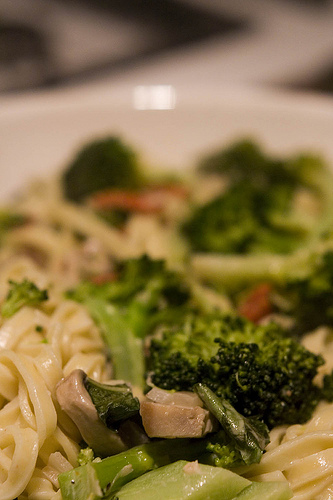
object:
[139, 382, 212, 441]
brown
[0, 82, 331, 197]
plate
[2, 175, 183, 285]
noodles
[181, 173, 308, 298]
broccoli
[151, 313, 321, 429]
broccoli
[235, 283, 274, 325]
red vegetable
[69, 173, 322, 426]
vegetable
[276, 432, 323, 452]
noodle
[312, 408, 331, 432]
noodle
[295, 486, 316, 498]
noodle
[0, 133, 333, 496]
food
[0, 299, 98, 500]
noodles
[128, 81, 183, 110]
light